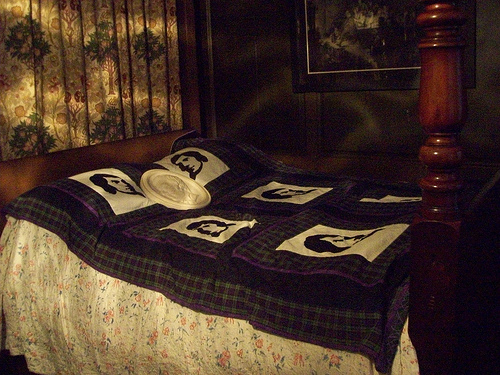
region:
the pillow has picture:
[301, 216, 453, 313]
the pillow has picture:
[299, 194, 389, 284]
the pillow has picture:
[279, 201, 406, 332]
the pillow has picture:
[146, 141, 283, 223]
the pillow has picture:
[167, 121, 252, 252]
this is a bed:
[130, 160, 362, 353]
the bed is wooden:
[429, 94, 462, 278]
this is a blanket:
[183, 211, 273, 283]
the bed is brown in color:
[423, 64, 463, 125]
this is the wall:
[223, 30, 279, 99]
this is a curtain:
[38, 22, 148, 100]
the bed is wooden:
[18, 159, 58, 179]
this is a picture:
[301, 5, 413, 87]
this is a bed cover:
[31, 298, 96, 372]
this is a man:
[89, 164, 123, 196]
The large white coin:
[138, 166, 215, 213]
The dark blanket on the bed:
[1, 128, 481, 373]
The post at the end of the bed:
[407, 3, 498, 373]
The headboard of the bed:
[0, 0, 205, 237]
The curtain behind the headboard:
[0, 1, 187, 161]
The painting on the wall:
[282, 0, 481, 95]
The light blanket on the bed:
[1, 211, 418, 373]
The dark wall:
[196, 2, 498, 192]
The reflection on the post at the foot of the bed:
[426, 3, 443, 217]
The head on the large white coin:
[153, 173, 200, 205]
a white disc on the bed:
[138, 154, 213, 209]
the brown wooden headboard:
[0, 122, 202, 207]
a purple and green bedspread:
[3, 128, 426, 373]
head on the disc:
[150, 166, 204, 204]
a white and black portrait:
[156, 209, 258, 250]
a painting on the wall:
[281, 2, 481, 100]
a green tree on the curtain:
[129, 20, 169, 67]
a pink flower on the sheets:
[250, 333, 267, 351]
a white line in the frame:
[299, 0, 423, 77]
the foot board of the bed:
[466, 171, 498, 373]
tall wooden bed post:
[419, 0, 466, 374]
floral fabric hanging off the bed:
[19, 273, 92, 350]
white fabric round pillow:
[141, 167, 210, 205]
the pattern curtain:
[17, 25, 141, 88]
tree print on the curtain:
[81, 16, 124, 96]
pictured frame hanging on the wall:
[287, 1, 479, 96]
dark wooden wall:
[213, 19, 287, 138]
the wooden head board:
[6, 122, 223, 206]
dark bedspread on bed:
[18, 130, 415, 345]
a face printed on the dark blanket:
[72, 164, 143, 214]